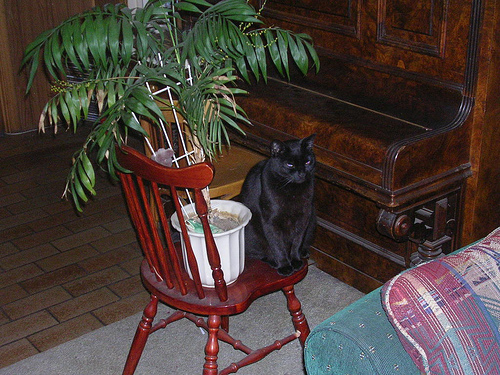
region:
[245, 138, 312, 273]
A black cat sitting on a chair.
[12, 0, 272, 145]
A miniature palm tree.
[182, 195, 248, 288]
White ceramic pot sitting on a chair.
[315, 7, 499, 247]
An antique piano in the living room.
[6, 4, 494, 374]
A nice and quiet living room.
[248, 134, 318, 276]
A tired black cat.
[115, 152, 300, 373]
Wooden chair sitting in the living room.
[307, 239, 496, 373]
Green and flowery sofa.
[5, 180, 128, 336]
Ceramic and brown floor.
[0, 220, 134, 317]
brown and rectangle tiles.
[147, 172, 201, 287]
The back of a wooden chair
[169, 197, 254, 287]
A white plant container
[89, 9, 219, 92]
The leaves of a green plant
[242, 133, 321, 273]
A black cat sitting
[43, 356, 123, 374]
A grey carpet on the floor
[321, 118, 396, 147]
The cover of a piano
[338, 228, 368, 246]
A layer of dust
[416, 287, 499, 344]
A cushion on the sofa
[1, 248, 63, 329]
A brown brick floor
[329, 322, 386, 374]
The arm of a sofa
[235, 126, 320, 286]
black cat sitting on chair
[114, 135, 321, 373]
chair with cat on it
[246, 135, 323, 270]
black cat sitting down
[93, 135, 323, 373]
brow wooden chair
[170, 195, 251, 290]
white potted plant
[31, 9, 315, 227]
green plants growing from pot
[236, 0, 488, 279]
brown wooden piano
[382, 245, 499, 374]
pink and white pillow on couch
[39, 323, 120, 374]
grey carpet on ground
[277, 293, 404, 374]
blue couch with white symbols on it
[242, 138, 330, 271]
Black cat on chair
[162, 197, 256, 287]
White pot with plant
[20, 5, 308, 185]
Tall green leafy plant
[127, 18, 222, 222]
White wires holding plant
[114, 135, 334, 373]
Shiny wooden chair on floor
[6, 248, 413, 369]
Gray carpet on floor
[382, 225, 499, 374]
Plaid pillow on chair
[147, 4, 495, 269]
Wooden piano against wall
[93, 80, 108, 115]
Dead leaf on plant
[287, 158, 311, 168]
Yellow eyes on cat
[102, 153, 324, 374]
brown chair on ground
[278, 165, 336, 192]
white whiskers of cat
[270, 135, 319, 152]
pointy black ears of cat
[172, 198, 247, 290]
white pot of plant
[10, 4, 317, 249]
large green plant in pot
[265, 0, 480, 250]
brown piano in background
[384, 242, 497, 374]
red and white striped pillow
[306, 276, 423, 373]
blue couch with white symbols